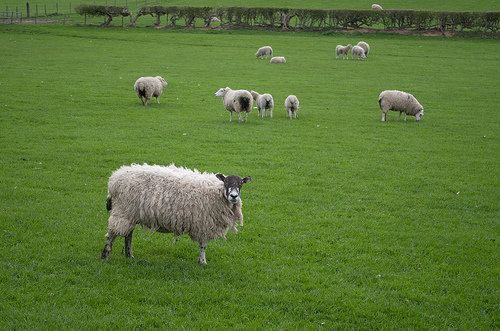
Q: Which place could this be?
A: It is a field.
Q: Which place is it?
A: It is a field.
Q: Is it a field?
A: Yes, it is a field.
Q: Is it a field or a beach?
A: It is a field.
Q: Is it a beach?
A: No, it is a field.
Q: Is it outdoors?
A: Yes, it is outdoors.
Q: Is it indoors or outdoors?
A: It is outdoors.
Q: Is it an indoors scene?
A: No, it is outdoors.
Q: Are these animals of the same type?
A: Yes, all the animals are sheep.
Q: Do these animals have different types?
A: No, all the animals are sheep.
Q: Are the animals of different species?
A: No, all the animals are sheep.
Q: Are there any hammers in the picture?
A: No, there are no hammers.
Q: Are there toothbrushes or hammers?
A: No, there are no hammers or toothbrushes.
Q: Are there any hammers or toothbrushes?
A: No, there are no hammers or toothbrushes.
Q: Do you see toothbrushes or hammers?
A: No, there are no hammers or toothbrushes.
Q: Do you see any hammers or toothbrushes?
A: No, there are no hammers or toothbrushes.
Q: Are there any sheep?
A: Yes, there is a sheep.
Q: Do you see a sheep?
A: Yes, there is a sheep.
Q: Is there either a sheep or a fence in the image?
A: Yes, there is a sheep.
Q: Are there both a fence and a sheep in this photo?
A: Yes, there are both a sheep and a fence.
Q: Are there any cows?
A: No, there are no cows.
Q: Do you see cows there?
A: No, there are no cows.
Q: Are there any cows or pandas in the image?
A: No, there are no cows or pandas.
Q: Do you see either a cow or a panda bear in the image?
A: No, there are no cows or pandas.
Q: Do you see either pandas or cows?
A: No, there are no cows or pandas.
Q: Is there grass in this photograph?
A: Yes, there is grass.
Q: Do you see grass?
A: Yes, there is grass.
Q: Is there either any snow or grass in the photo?
A: Yes, there is grass.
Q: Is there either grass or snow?
A: Yes, there is grass.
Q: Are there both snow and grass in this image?
A: No, there is grass but no snow.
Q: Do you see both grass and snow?
A: No, there is grass but no snow.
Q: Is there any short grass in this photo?
A: Yes, there is short grass.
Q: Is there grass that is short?
A: Yes, there is grass that is short.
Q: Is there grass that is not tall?
A: Yes, there is short grass.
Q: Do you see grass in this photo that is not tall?
A: Yes, there is short grass.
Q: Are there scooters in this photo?
A: No, there are no scooters.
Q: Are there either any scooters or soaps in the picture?
A: No, there are no scooters or soaps.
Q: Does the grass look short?
A: Yes, the grass is short.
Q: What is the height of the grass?
A: The grass is short.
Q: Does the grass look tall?
A: No, the grass is short.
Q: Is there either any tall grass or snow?
A: No, there is grass but it is short.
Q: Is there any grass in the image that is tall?
A: No, there is grass but it is short.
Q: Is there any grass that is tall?
A: No, there is grass but it is short.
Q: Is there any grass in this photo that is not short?
A: No, there is grass but it is short.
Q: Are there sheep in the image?
A: Yes, there is a sheep.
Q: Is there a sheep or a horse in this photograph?
A: Yes, there is a sheep.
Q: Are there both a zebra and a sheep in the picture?
A: No, there is a sheep but no zebras.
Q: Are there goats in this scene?
A: No, there are no goats.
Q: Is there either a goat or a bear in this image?
A: No, there are no goats or bears.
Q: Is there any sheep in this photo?
A: Yes, there is a sheep.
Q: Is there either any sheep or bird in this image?
A: Yes, there is a sheep.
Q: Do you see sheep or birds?
A: Yes, there is a sheep.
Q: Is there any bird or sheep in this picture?
A: Yes, there is a sheep.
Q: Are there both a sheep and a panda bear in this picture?
A: No, there is a sheep but no panda bears.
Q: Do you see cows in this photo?
A: No, there are no cows.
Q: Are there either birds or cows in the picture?
A: No, there are no cows or birds.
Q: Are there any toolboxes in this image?
A: No, there are no toolboxes.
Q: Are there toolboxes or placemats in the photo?
A: No, there are no toolboxes or placemats.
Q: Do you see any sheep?
A: Yes, there is a sheep.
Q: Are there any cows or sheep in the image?
A: Yes, there is a sheep.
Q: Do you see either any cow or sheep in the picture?
A: Yes, there is a sheep.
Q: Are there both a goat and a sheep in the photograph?
A: No, there is a sheep but no goats.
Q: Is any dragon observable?
A: No, there are no dragons.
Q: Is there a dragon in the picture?
A: No, there are no dragons.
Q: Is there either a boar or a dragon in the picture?
A: No, there are no dragons or boars.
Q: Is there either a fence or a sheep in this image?
A: Yes, there is a sheep.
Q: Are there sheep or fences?
A: Yes, there is a sheep.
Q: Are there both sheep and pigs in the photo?
A: No, there is a sheep but no pigs.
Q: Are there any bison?
A: No, there are no bison.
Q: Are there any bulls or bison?
A: No, there are no bison or bulls.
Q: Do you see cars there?
A: No, there are no cars.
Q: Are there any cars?
A: No, there are no cars.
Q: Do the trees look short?
A: Yes, the trees are short.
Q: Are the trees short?
A: Yes, the trees are short.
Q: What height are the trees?
A: The trees are short.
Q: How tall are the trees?
A: The trees are short.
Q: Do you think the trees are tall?
A: No, the trees are short.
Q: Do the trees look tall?
A: No, the trees are short.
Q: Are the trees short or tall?
A: The trees are short.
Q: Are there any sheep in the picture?
A: Yes, there is a sheep.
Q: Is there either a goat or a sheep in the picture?
A: Yes, there is a sheep.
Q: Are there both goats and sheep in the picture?
A: No, there is a sheep but no goats.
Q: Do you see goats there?
A: No, there are no goats.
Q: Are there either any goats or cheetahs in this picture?
A: No, there are no goats or cheetahs.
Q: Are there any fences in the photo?
A: Yes, there is a fence.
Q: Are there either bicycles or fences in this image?
A: Yes, there is a fence.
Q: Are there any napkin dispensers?
A: No, there are no napkin dispensers.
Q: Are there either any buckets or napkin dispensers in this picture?
A: No, there are no napkin dispensers or buckets.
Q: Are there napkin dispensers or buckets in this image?
A: No, there are no napkin dispensers or buckets.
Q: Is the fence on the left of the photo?
A: Yes, the fence is on the left of the image.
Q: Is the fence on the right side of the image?
A: No, the fence is on the left of the image.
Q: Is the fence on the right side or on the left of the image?
A: The fence is on the left of the image.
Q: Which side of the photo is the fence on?
A: The fence is on the left of the image.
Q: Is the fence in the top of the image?
A: Yes, the fence is in the top of the image.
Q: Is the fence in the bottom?
A: No, the fence is in the top of the image.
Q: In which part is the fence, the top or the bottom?
A: The fence is in the top of the image.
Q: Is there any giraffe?
A: No, there are no giraffes.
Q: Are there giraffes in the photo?
A: No, there are no giraffes.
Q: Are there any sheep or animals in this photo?
A: Yes, there is a sheep.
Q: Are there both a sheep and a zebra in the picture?
A: No, there is a sheep but no zebras.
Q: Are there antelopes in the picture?
A: No, there are no antelopes.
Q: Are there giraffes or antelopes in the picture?
A: No, there are no antelopes or giraffes.